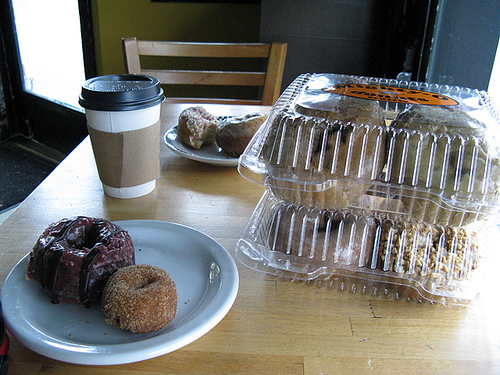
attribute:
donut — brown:
[92, 235, 201, 340]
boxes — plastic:
[236, 69, 498, 311]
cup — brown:
[78, 72, 183, 199]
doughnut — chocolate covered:
[27, 216, 135, 303]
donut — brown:
[11, 202, 145, 309]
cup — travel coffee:
[77, 70, 165, 201]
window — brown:
[9, 0, 91, 117]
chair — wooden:
[118, 29, 289, 109]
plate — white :
[175, 227, 225, 301]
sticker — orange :
[322, 80, 462, 107]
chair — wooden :
[118, 36, 288, 105]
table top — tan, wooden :
[0, 102, 488, 374]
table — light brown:
[263, 273, 422, 373]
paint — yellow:
[92, 0, 268, 115]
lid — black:
[72, 75, 148, 108]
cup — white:
[75, 66, 172, 202]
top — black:
[72, 68, 168, 111]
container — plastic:
[244, 184, 499, 299]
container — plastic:
[254, 68, 499, 216]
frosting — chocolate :
[30, 216, 128, 301]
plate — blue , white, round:
[0, 210, 239, 373]